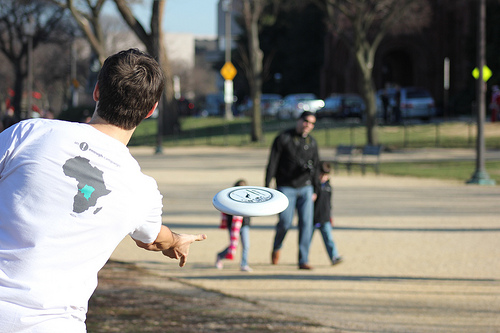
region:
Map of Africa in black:
[54, 150, 114, 222]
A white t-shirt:
[0, 115, 164, 331]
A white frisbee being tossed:
[211, 178, 297, 225]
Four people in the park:
[0, 44, 338, 331]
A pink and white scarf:
[214, 205, 247, 268]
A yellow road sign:
[215, 57, 244, 89]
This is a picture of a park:
[2, 4, 494, 326]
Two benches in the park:
[309, 129, 396, 183]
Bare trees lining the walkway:
[7, 0, 451, 146]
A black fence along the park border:
[129, 117, 474, 157]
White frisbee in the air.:
[201, 164, 318, 253]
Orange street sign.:
[216, 35, 241, 112]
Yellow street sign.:
[463, 51, 498, 116]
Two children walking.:
[211, 153, 346, 287]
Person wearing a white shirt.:
[0, 41, 209, 331]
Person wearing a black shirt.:
[260, 105, 325, 200]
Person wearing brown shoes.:
[257, 105, 327, 271]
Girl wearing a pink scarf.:
[205, 165, 255, 280]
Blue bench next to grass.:
[320, 137, 385, 177]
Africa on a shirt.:
[0, 115, 167, 330]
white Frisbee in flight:
[207, 178, 306, 225]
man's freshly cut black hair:
[95, 49, 167, 121]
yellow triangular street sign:
[210, 56, 247, 83]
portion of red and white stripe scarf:
[227, 217, 247, 262]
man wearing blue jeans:
[270, 182, 317, 257]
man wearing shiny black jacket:
[263, 125, 322, 192]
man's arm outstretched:
[133, 190, 209, 274]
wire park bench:
[331, 137, 386, 170]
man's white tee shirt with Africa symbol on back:
[13, 119, 163, 278]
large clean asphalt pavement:
[367, 199, 481, 274]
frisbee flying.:
[213, 187, 290, 217]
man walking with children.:
[263, 111, 319, 269]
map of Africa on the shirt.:
[60, 153, 115, 214]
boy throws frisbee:
[1, 44, 206, 331]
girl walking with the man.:
[215, 178, 255, 273]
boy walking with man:
[312, 160, 343, 272]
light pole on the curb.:
[466, 3, 495, 188]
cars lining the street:
[243, 95, 438, 120]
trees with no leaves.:
[5, 3, 77, 115]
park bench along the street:
[324, 142, 387, 174]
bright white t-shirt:
[1, 119, 165, 331]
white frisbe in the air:
[208, 182, 295, 222]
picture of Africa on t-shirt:
[60, 152, 112, 222]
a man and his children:
[208, 101, 348, 272]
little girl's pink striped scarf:
[216, 207, 243, 262]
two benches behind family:
[319, 139, 383, 180]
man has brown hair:
[93, 45, 168, 132]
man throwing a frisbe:
[1, 44, 208, 331]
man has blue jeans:
[270, 182, 318, 269]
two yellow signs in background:
[221, 59, 493, 95]